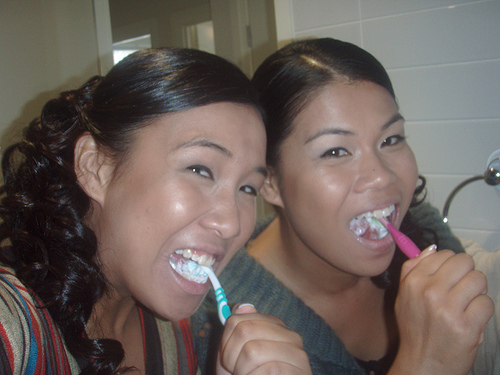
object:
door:
[107, 0, 283, 79]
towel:
[445, 229, 500, 314]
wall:
[279, 0, 500, 375]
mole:
[368, 165, 380, 175]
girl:
[195, 27, 500, 375]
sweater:
[183, 215, 499, 375]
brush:
[377, 212, 422, 258]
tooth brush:
[197, 264, 235, 326]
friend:
[0, 43, 278, 375]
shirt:
[0, 246, 207, 375]